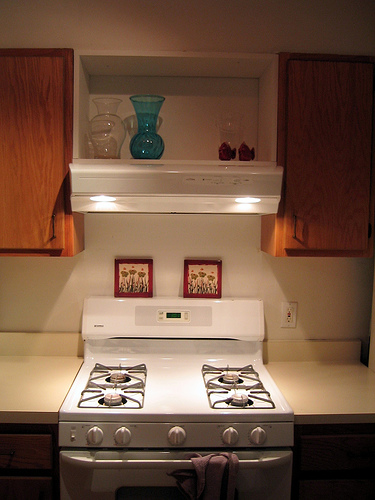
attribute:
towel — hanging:
[183, 451, 244, 496]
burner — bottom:
[206, 383, 275, 411]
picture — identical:
[116, 257, 152, 295]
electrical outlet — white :
[277, 299, 300, 330]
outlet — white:
[277, 297, 298, 328]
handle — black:
[50, 215, 55, 239]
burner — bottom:
[83, 380, 144, 408]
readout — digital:
[166, 313, 182, 318]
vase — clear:
[79, 94, 125, 156]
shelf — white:
[66, 157, 283, 217]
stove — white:
[51, 291, 297, 425]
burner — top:
[80, 357, 145, 391]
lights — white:
[76, 179, 276, 228]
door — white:
[58, 448, 296, 498]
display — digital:
[156, 306, 190, 324]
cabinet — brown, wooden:
[258, 55, 373, 258]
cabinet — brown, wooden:
[0, 43, 87, 255]